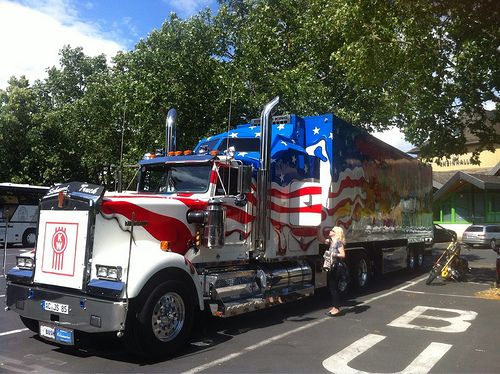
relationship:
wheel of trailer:
[324, 248, 356, 295] [269, 93, 440, 316]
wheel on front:
[324, 248, 356, 295] [317, 113, 377, 294]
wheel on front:
[345, 244, 372, 294] [317, 113, 377, 294]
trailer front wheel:
[269, 93, 440, 316] [345, 244, 372, 294]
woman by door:
[324, 224, 346, 321] [217, 159, 250, 250]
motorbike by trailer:
[429, 236, 471, 283] [269, 93, 440, 316]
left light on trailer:
[97, 264, 120, 280] [269, 93, 440, 316]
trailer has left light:
[269, 93, 440, 316] [97, 264, 120, 280]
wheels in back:
[406, 243, 428, 271] [408, 156, 443, 273]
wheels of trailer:
[406, 243, 428, 271] [269, 93, 440, 316]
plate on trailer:
[38, 323, 59, 341] [269, 93, 440, 316]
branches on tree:
[227, 0, 499, 164] [3, 0, 500, 187]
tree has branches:
[3, 0, 500, 187] [227, 0, 499, 164]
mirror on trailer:
[236, 164, 256, 197] [269, 93, 440, 316]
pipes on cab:
[163, 95, 283, 251] [6, 92, 281, 350]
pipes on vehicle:
[163, 95, 283, 251] [5, 93, 441, 350]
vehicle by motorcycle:
[5, 93, 441, 350] [427, 230, 474, 281]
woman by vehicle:
[324, 224, 346, 321] [5, 93, 441, 350]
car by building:
[462, 221, 498, 250] [402, 107, 499, 246]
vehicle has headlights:
[5, 93, 441, 350] [15, 260, 122, 283]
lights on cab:
[149, 148, 227, 156] [6, 92, 281, 350]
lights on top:
[149, 148, 227, 156] [141, 141, 266, 161]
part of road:
[411, 229, 500, 265] [435, 231, 498, 262]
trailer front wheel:
[269, 93, 440, 316] [133, 271, 197, 363]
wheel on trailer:
[133, 271, 197, 363] [269, 93, 440, 316]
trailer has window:
[269, 93, 440, 316] [138, 157, 214, 197]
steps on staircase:
[209, 288, 260, 317] [207, 259, 267, 314]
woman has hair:
[324, 224, 346, 321] [333, 227, 345, 249]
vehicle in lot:
[5, 93, 441, 350] [2, 185, 499, 373]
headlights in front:
[15, 260, 122, 283] [6, 180, 126, 348]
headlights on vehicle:
[15, 260, 122, 283] [5, 93, 434, 351]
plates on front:
[39, 325, 55, 345] [6, 180, 126, 348]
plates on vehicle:
[39, 325, 55, 345] [5, 93, 434, 351]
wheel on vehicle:
[133, 271, 197, 363] [5, 93, 434, 351]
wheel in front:
[133, 271, 197, 363] [6, 180, 126, 348]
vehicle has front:
[5, 93, 434, 351] [6, 180, 126, 348]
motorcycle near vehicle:
[427, 230, 474, 281] [5, 93, 441, 350]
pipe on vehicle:
[249, 94, 284, 259] [5, 93, 434, 351]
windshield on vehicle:
[137, 164, 210, 192] [5, 93, 434, 351]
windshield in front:
[137, 164, 210, 192] [6, 180, 126, 348]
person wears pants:
[328, 224, 345, 317] [324, 266, 342, 308]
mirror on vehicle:
[236, 164, 256, 197] [5, 93, 434, 351]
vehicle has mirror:
[5, 93, 434, 351] [236, 164, 256, 197]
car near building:
[462, 221, 498, 250] [402, 107, 499, 246]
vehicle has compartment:
[5, 93, 441, 350] [288, 184, 326, 231]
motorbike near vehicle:
[425, 236, 471, 286] [5, 93, 441, 350]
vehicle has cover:
[5, 93, 441, 350] [33, 211, 87, 289]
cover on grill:
[33, 211, 87, 289] [37, 181, 105, 293]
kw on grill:
[49, 229, 73, 252] [37, 181, 105, 293]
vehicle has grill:
[5, 93, 441, 350] [37, 181, 105, 293]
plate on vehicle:
[38, 323, 59, 341] [5, 93, 441, 350]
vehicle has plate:
[5, 93, 441, 350] [38, 323, 59, 341]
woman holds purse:
[324, 224, 346, 321] [329, 257, 351, 285]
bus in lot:
[0, 172, 42, 249] [2, 185, 499, 373]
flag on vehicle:
[100, 114, 355, 242] [5, 93, 441, 350]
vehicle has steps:
[5, 93, 441, 350] [209, 288, 260, 317]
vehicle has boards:
[5, 93, 441, 350] [213, 261, 270, 315]